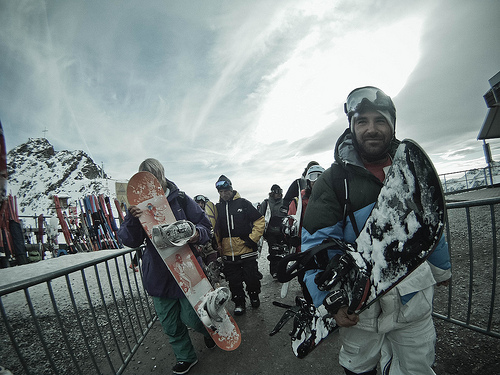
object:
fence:
[0, 244, 158, 375]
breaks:
[201, 55, 234, 106]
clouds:
[247, 19, 329, 140]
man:
[300, 86, 452, 375]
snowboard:
[291, 138, 447, 359]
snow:
[370, 237, 382, 276]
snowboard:
[126, 171, 241, 352]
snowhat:
[343, 86, 395, 140]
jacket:
[205, 190, 266, 262]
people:
[118, 158, 217, 375]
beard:
[358, 133, 391, 155]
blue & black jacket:
[300, 128, 450, 335]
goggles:
[343, 86, 394, 116]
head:
[343, 85, 396, 154]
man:
[205, 174, 265, 315]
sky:
[221, 46, 329, 128]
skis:
[51, 194, 124, 254]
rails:
[0, 286, 130, 361]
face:
[154, 176, 161, 186]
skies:
[9, 71, 269, 136]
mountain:
[440, 160, 499, 196]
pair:
[346, 87, 390, 116]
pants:
[338, 317, 435, 375]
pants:
[149, 296, 210, 362]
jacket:
[116, 178, 214, 298]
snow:
[35, 165, 48, 178]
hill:
[6, 137, 130, 244]